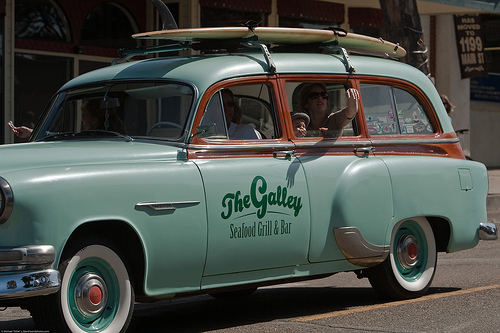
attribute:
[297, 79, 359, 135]
woman — waving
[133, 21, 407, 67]
surfboard — white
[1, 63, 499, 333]
car — aqua colored, old style, green, mint green, vintage, antique, woody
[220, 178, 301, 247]
writing — green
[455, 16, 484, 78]
sign — black, white, notifying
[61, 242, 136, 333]
tire — white walled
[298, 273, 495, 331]
line — yellow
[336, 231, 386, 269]
fender — silver, chrome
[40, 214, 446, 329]
tires — light green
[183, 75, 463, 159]
trim — wood